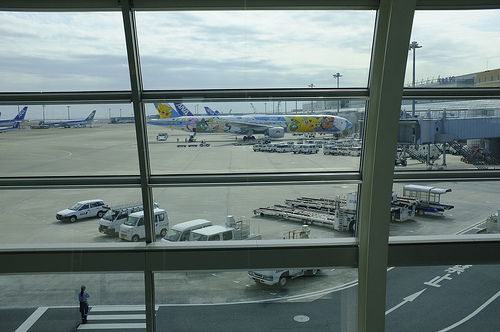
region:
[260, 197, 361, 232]
trucks near the gate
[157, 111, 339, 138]
plane with printed pictures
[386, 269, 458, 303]
lines in the road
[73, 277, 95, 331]
female standing watching plane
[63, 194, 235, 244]
cars lined up for planes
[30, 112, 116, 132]
blue plane in the background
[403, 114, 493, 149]
boarding gate for the passengers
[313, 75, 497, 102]
airport terminal above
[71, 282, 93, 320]
person walking out side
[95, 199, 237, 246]
agroup of part van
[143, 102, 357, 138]
pretty design air plane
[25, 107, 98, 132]
there is a air plane on the run way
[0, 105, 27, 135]
a nother air plane on the run way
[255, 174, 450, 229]
bags carrier trucks park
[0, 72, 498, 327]
this is a large air port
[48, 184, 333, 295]
cars and vans in parking lot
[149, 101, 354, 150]
colorful airplane at airport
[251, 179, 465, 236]
utility trucks seen through window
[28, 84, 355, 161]
airplanes at airport seen through window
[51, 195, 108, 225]
car parked on concrete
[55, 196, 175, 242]
one white car and two white vans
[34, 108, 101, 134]
airplane on concrete in distance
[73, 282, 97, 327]
person crossing at crosswalk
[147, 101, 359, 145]
airplane painted with picachu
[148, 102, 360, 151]
jet airliner with pokemon themed paint job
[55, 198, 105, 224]
a small white car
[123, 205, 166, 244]
a small white van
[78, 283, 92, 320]
a woman in blue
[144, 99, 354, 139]
a plane with pokemon on it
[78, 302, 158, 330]
white stripes on the road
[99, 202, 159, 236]
a white van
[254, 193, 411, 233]
large white trucks are parked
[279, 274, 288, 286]
wheel on a truck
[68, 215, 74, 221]
wheel on a car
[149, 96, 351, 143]
the plane has many colors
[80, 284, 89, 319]
the person is standing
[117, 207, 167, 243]
the car is parked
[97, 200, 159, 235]
the car is parked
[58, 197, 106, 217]
the car is parked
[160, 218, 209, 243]
the car is parked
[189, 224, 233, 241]
the car is parked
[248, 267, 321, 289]
the car is parked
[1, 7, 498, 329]
the window has frames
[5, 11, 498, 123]
the sky is cloudy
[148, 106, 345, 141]
pikachu plane on runway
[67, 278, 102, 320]
person walking on the sidewalk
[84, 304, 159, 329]
the striped crosswalk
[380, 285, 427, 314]
white arrow on the road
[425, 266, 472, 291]
chinese writing on the road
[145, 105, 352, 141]
the colorful plane in the front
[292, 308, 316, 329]
the manhole on the road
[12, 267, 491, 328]
the black top road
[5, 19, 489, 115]
the cloudy blue sky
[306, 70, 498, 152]
the buildings by the planes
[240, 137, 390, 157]
vans parked by the planes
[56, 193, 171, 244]
Cars parked in a row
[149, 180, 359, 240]
Window on a building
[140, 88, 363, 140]
Bright painting on plane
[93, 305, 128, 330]
White paint on road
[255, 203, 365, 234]
Truck on the runway